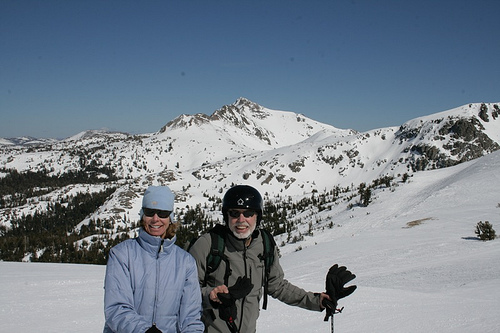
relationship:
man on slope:
[191, 183, 327, 332] [3, 195, 496, 333]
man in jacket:
[191, 183, 327, 332] [186, 226, 320, 332]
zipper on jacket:
[235, 241, 248, 332] [186, 226, 320, 332]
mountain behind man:
[149, 95, 335, 162] [191, 183, 327, 332]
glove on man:
[323, 263, 355, 322] [191, 183, 327, 332]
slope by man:
[3, 195, 496, 333] [191, 183, 327, 332]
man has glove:
[191, 183, 327, 332] [323, 263, 355, 322]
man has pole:
[191, 183, 327, 332] [324, 295, 339, 332]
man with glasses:
[191, 183, 327, 332] [227, 209, 256, 218]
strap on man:
[202, 222, 224, 278] [191, 183, 327, 332]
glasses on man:
[227, 209, 256, 218] [191, 183, 327, 332]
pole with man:
[324, 295, 339, 332] [191, 183, 327, 332]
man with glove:
[191, 183, 327, 332] [323, 263, 355, 322]